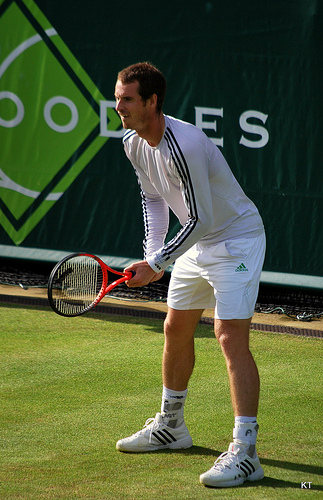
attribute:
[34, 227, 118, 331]
tennis racket — black, orange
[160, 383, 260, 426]
splints — velcro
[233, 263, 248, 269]
logo — large, light green, triangle shaped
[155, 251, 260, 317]
tennis shorts — white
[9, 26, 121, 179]
sign — green, fabric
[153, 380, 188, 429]
sock — tall, white, grey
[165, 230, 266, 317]
shorts — white adidas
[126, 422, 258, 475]
stripes — black, three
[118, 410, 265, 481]
shoes — white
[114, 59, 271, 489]
player — tennis, white, readying for play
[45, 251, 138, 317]
racket — tennis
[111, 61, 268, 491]
shirt — white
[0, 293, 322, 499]
tennis court — green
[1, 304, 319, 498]
tenniscourt — green, grassy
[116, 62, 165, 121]
hair — short, brown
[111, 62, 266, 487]
tennis player — ready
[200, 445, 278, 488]
tennis shoes — white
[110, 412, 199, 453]
tennis shoes — white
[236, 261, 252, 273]
logo — green, adidas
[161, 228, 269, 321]
shorts — white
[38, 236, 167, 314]
racket — tennis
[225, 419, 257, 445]
sock — black, white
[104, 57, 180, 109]
hair — short, dark brown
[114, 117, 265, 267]
shirt — white, long sleeved, adidas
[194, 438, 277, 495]
shoe — white, tennis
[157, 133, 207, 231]
stripes — multiple, black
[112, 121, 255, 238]
shirt — white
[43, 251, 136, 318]
tennis racket — black, red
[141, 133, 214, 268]
stripes — three, black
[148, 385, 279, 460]
socks — player's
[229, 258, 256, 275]
logo — green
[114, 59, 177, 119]
hair — short, brown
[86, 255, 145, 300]
handle — red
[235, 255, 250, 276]
symbol — brand name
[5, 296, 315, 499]
court — grass, grassy, tennis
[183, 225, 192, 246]
stripes — black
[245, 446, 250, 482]
stripes — black adidas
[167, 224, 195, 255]
stripes — black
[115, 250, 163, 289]
hands — both